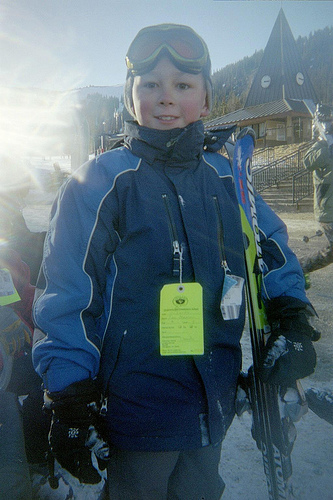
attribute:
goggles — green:
[119, 18, 214, 73]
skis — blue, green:
[226, 127, 296, 493]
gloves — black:
[40, 373, 115, 487]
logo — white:
[65, 426, 80, 438]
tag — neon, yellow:
[156, 278, 207, 357]